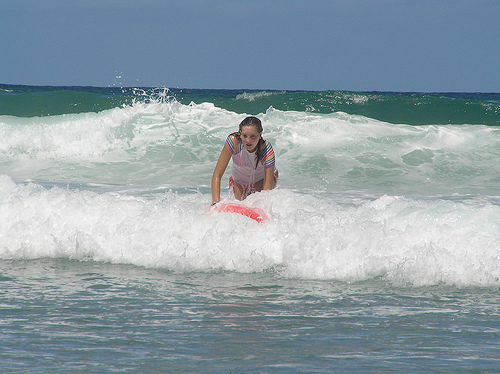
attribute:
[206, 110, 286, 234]
girl — with brown hair, on a surfboard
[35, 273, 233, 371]
calmer/rippled water — in front of the waves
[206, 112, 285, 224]
girl — on orange surfboard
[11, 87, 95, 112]
greenest section — of water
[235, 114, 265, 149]
head — of a girl, on a surfboard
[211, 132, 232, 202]
right arm — of a girl surfer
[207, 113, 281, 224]
woman — in the water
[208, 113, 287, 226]
woman — on a surfboard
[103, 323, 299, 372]
small ripples — in the water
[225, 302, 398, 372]
small ripples — in the water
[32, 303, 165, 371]
small ripples — in the water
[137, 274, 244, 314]
small ripples — in the water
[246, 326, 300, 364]
small ripples — in the water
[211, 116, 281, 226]
girl — in the water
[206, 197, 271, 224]
red surfboard — in the water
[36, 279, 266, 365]
small ripples — in the water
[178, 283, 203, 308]
ripples — Small 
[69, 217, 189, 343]
ripples — Small 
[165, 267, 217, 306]
ripples — Small 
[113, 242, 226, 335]
ripples — Small 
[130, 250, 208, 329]
ripples — Small 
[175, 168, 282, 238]
surfboard — red 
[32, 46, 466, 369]
water — blue , dark 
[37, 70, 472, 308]
wave — rolling 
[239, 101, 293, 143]
hair — brunette 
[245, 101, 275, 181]
hair — long 